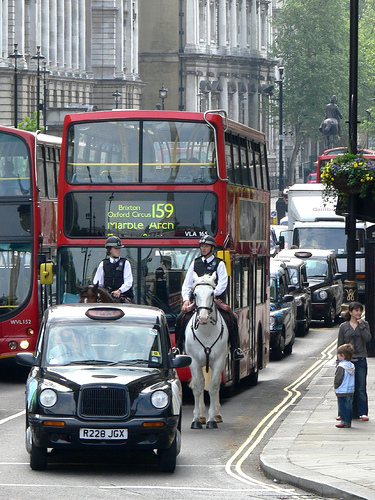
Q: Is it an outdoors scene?
A: Yes, it is outdoors.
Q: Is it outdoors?
A: Yes, it is outdoors.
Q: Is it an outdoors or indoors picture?
A: It is outdoors.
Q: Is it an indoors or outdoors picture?
A: It is outdoors.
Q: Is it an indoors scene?
A: No, it is outdoors.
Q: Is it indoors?
A: No, it is outdoors.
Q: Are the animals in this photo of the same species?
A: Yes, all the animals are horses.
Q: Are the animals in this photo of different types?
A: No, all the animals are horses.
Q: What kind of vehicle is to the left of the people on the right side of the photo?
A: The vehicle is a car.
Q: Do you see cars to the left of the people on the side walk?
A: Yes, there is a car to the left of the people.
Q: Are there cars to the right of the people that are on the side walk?
A: No, the car is to the left of the people.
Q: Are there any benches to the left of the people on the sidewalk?
A: No, there is a car to the left of the people.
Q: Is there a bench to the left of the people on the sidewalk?
A: No, there is a car to the left of the people.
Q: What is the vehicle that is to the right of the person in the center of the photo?
A: The vehicle is a car.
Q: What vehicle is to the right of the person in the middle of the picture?
A: The vehicle is a car.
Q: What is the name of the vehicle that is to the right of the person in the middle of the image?
A: The vehicle is a car.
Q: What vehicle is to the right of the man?
A: The vehicle is a car.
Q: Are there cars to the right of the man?
A: Yes, there is a car to the right of the man.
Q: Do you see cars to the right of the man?
A: Yes, there is a car to the right of the man.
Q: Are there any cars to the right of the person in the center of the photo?
A: Yes, there is a car to the right of the man.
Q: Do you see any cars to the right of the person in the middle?
A: Yes, there is a car to the right of the man.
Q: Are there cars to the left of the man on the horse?
A: No, the car is to the right of the man.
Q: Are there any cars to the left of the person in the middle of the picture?
A: No, the car is to the right of the man.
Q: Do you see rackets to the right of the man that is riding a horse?
A: No, there is a car to the right of the man.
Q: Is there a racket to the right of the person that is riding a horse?
A: No, there is a car to the right of the man.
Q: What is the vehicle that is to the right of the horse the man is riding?
A: The vehicle is a car.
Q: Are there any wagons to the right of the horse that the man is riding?
A: No, there is a car to the right of the horse.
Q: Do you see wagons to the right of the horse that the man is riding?
A: No, there is a car to the right of the horse.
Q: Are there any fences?
A: No, there are no fences.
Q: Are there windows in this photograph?
A: Yes, there is a window.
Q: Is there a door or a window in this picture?
A: Yes, there is a window.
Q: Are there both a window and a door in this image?
A: Yes, there are both a window and a door.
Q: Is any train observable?
A: No, there are no trains.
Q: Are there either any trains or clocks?
A: No, there are no trains or clocks.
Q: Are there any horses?
A: Yes, there is a horse.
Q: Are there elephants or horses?
A: Yes, there is a horse.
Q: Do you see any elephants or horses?
A: Yes, there is a horse.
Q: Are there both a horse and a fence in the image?
A: No, there is a horse but no fences.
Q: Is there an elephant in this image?
A: No, there are no elephants.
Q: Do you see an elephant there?
A: No, there are no elephants.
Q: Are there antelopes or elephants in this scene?
A: No, there are no elephants or antelopes.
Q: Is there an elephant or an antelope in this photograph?
A: No, there are no elephants or antelopes.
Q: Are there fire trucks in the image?
A: No, there are no fire trucks.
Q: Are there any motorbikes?
A: No, there are no motorbikes.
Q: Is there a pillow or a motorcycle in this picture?
A: No, there are no motorcycles or pillows.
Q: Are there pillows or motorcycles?
A: No, there are no motorcycles or pillows.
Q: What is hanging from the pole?
A: The plant is hanging from the pole.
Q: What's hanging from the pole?
A: The plant is hanging from the pole.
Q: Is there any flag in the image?
A: No, there are no flags.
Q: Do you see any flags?
A: No, there are no flags.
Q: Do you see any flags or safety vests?
A: No, there are no flags or safety vests.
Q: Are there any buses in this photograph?
A: Yes, there are buses.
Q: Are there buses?
A: Yes, there are buses.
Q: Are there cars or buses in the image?
A: Yes, there are buses.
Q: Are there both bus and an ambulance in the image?
A: No, there are buses but no ambulances.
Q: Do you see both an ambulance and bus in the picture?
A: No, there are buses but no ambulances.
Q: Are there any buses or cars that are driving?
A: Yes, the buses are driving.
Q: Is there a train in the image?
A: No, there are no trains.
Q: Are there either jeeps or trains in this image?
A: No, there are no trains or jeeps.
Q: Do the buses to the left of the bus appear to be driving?
A: Yes, the buses are driving.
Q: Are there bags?
A: No, there are no bags.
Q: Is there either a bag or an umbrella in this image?
A: No, there are no bags or umbrellas.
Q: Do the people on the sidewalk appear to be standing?
A: Yes, the people are standing.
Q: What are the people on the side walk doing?
A: The people are standing.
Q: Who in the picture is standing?
A: The people are standing.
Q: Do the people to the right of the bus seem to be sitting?
A: No, the people are standing.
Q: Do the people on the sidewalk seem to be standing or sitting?
A: The people are standing.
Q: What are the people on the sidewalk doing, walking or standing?
A: The people are standing.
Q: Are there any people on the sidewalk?
A: Yes, there are people on the sidewalk.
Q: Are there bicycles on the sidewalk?
A: No, there are people on the sidewalk.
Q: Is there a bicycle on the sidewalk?
A: No, there are people on the sidewalk.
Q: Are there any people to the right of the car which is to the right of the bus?
A: Yes, there are people to the right of the car.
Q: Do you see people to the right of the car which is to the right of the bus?
A: Yes, there are people to the right of the car.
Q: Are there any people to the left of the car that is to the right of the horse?
A: No, the people are to the right of the car.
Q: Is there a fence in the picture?
A: No, there are no fences.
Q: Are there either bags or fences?
A: No, there are no fences or bags.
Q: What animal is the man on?
A: The man is on the horse.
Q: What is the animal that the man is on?
A: The animal is a horse.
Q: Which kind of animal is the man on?
A: The man is on the horse.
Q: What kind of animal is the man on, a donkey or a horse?
A: The man is on a horse.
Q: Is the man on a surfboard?
A: No, the man is on the horse.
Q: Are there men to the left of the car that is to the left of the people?
A: Yes, there is a man to the left of the car.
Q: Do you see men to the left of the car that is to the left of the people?
A: Yes, there is a man to the left of the car.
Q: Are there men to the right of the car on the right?
A: No, the man is to the left of the car.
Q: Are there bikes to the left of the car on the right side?
A: No, there is a man to the left of the car.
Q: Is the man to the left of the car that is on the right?
A: Yes, the man is to the left of the car.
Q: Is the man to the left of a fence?
A: No, the man is to the left of the car.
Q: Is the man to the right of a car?
A: No, the man is to the left of a car.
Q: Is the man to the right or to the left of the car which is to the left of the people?
A: The man is to the left of the car.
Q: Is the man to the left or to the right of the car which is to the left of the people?
A: The man is to the left of the car.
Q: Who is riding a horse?
A: The man is riding a horse.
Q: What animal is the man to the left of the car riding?
A: The man is riding a horse.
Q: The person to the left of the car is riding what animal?
A: The man is riding a horse.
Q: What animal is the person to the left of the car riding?
A: The man is riding a horse.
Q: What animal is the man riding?
A: The man is riding a horse.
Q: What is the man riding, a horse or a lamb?
A: The man is riding a horse.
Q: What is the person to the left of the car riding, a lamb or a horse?
A: The man is riding a horse.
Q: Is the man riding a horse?
A: Yes, the man is riding a horse.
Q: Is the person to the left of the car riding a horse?
A: Yes, the man is riding a horse.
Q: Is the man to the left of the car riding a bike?
A: No, the man is riding a horse.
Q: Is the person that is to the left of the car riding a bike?
A: No, the man is riding a horse.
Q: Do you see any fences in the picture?
A: No, there are no fences.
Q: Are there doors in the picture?
A: Yes, there are doors.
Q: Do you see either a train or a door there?
A: Yes, there are doors.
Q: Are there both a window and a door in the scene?
A: Yes, there are both a door and a window.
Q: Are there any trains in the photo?
A: No, there are no trains.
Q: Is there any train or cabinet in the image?
A: No, there are no trains or cabinets.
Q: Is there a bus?
A: Yes, there is a bus.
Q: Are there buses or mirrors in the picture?
A: Yes, there is a bus.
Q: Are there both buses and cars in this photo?
A: Yes, there are both a bus and a car.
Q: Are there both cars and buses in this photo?
A: Yes, there are both a bus and a car.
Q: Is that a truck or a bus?
A: That is a bus.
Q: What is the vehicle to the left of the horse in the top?
A: The vehicle is a bus.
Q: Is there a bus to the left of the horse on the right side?
A: Yes, there is a bus to the left of the horse.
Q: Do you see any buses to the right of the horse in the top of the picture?
A: No, the bus is to the left of the horse.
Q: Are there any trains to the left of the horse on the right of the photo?
A: No, there is a bus to the left of the horse.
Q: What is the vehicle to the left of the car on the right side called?
A: The vehicle is a bus.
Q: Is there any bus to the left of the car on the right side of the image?
A: Yes, there is a bus to the left of the car.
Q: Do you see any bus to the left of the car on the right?
A: Yes, there is a bus to the left of the car.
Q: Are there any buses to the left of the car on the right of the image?
A: Yes, there is a bus to the left of the car.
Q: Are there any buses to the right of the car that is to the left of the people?
A: No, the bus is to the left of the car.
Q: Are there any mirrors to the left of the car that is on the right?
A: No, there is a bus to the left of the car.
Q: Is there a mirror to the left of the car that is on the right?
A: No, there is a bus to the left of the car.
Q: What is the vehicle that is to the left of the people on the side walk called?
A: The vehicle is a bus.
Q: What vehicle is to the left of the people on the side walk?
A: The vehicle is a bus.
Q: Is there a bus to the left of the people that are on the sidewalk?
A: Yes, there is a bus to the left of the people.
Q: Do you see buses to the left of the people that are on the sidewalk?
A: Yes, there is a bus to the left of the people.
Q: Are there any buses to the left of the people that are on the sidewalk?
A: Yes, there is a bus to the left of the people.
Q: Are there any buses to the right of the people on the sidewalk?
A: No, the bus is to the left of the people.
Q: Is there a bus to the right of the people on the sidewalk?
A: No, the bus is to the left of the people.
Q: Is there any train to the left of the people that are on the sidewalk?
A: No, there is a bus to the left of the people.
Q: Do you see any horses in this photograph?
A: Yes, there is a horse.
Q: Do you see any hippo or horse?
A: Yes, there is a horse.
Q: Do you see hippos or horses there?
A: Yes, there is a horse.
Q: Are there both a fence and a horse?
A: No, there is a horse but no fences.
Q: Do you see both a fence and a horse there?
A: No, there is a horse but no fences.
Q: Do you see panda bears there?
A: No, there are no panda bears.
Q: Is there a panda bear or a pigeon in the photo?
A: No, there are no pandas or pigeons.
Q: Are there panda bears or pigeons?
A: No, there are no panda bears or pigeons.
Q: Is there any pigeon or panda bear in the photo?
A: No, there are no pandas or pigeons.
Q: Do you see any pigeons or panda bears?
A: No, there are no panda bears or pigeons.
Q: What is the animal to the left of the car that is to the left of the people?
A: The animal is a horse.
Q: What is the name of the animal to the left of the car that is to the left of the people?
A: The animal is a horse.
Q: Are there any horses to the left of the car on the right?
A: Yes, there is a horse to the left of the car.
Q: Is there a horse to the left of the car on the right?
A: Yes, there is a horse to the left of the car.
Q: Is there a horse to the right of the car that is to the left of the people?
A: No, the horse is to the left of the car.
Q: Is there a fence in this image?
A: No, there are no fences.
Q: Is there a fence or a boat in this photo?
A: No, there are no fences or boats.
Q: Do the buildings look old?
A: Yes, the buildings are old.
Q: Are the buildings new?
A: No, the buildings are old.